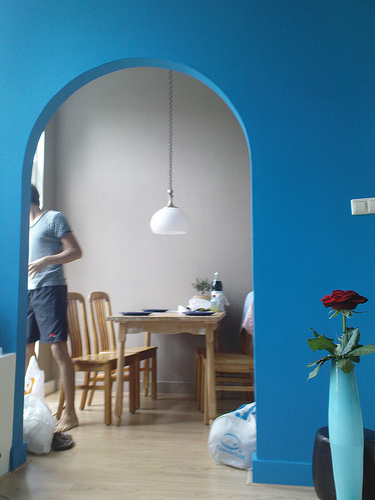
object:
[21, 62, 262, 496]
dining room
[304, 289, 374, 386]
rose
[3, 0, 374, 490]
wall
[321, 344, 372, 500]
vase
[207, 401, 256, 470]
bag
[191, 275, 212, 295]
tree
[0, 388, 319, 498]
floor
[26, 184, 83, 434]
man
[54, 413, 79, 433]
bare feet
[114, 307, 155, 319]
plate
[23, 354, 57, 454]
bag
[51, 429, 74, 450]
shoe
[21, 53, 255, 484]
doorway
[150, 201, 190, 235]
light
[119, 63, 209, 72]
ceiling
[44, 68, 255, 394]
wall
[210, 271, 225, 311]
bottle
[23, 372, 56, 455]
garbage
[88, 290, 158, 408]
chair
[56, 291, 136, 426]
chair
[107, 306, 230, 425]
table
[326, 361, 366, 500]
vase